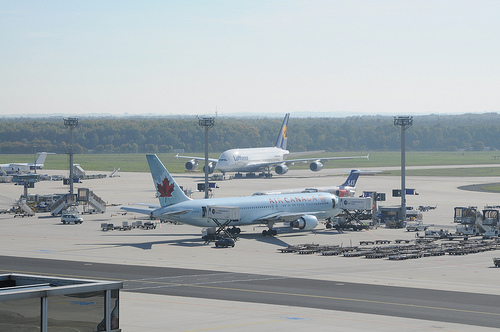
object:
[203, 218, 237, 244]
ramp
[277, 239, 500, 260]
pallets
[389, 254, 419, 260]
rack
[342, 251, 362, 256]
rack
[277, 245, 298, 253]
rack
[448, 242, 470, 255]
rack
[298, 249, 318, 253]
equipment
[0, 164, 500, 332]
runway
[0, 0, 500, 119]
sky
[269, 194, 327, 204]
logo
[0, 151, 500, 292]
ground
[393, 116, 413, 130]
lights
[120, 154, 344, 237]
airplane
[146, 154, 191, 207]
tail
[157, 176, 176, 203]
maple leaf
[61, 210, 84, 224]
van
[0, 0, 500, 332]
airport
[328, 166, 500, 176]
grass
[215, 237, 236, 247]
car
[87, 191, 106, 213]
stairs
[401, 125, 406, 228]
pole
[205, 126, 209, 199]
pole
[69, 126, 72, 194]
pole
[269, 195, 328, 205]
name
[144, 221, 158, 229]
carts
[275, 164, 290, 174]
engines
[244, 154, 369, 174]
wing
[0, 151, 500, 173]
field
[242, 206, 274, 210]
windows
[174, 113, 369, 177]
airplane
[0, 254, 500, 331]
tarmac